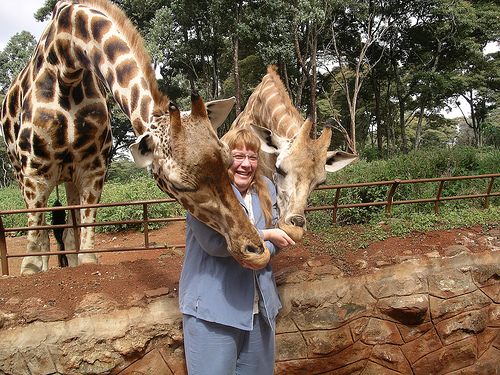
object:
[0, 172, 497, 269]
fence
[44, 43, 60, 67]
spot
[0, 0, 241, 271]
giraffe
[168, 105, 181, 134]
horn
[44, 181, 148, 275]
rail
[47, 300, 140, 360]
wall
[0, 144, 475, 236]
bushes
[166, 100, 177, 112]
horn tip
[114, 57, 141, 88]
spot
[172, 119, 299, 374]
woman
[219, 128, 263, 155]
bangs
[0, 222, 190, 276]
path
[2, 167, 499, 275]
railing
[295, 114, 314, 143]
horns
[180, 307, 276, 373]
pants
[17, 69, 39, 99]
spot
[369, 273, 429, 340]
stone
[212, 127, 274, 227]
hair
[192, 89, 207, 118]
horn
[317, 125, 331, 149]
horn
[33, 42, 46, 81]
spot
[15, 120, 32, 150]
spot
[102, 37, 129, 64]
spot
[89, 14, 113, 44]
spot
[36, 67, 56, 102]
spot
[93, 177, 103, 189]
spot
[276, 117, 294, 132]
spot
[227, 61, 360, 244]
giraffe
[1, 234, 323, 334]
dirt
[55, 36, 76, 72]
spot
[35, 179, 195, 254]
wall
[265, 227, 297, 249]
hand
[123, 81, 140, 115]
spot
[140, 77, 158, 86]
spot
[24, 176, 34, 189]
spot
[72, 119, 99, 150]
spot